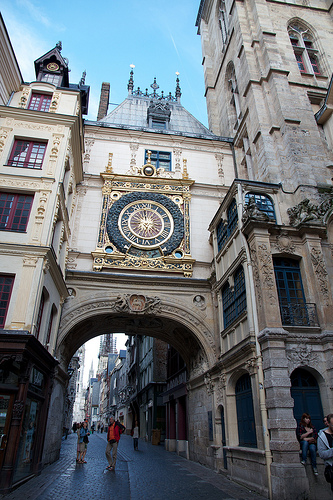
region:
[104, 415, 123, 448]
person in orange shirt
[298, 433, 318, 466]
girl wearing blue pants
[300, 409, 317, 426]
girl has brown hair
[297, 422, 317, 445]
girl wearing brown shirt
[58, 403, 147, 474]
people standing under building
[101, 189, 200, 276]
clock on side of building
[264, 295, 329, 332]
balcony on the building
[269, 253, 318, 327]
window on the building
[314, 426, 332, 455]
person wearing gray jacket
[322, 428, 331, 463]
person wearing black shirt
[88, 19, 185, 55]
this is the sky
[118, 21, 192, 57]
the sky is blue in color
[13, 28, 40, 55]
these are the clouds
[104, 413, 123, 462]
this is a man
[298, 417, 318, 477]
this is a lady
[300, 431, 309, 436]
the lady is light skinned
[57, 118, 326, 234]
this is a building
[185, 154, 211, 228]
this is the wall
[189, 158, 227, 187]
the wall is brown in color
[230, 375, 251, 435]
this is a window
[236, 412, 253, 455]
part of a window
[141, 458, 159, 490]
part of a road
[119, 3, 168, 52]
the sky is blue in color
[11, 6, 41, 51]
the sky has clouds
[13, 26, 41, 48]
the clouds are white in color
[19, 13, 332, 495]
this is a building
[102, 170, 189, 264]
this is a clock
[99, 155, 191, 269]
the clock is big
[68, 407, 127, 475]
these are some people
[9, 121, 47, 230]
these are some windows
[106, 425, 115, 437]
the jacket is red in color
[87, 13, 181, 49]
Sky is blue color.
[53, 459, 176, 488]
Road is grey color.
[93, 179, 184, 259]
clock is black and golden color.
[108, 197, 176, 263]
Numbers are in Roman letters.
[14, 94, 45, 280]
Windows are in building wall.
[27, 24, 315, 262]
Day time picture.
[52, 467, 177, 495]
Pathway is made of concrete bricks.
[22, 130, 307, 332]
Wall is brown color.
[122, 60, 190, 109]
tower is grey color.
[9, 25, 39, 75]
Clouds are white color.